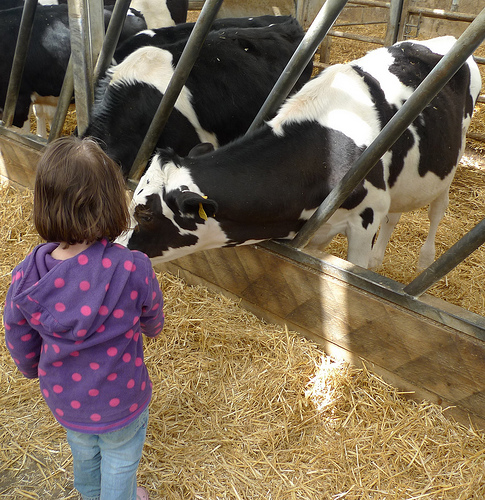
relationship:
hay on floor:
[1, 4, 483, 499] [0, 6, 483, 500]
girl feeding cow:
[2, 132, 169, 500] [104, 26, 483, 315]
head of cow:
[103, 141, 226, 277] [104, 26, 483, 315]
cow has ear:
[104, 26, 483, 315] [172, 185, 219, 223]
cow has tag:
[104, 26, 483, 315] [196, 192, 211, 223]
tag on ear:
[196, 192, 211, 223] [172, 185, 219, 223]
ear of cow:
[172, 185, 219, 223] [104, 26, 483, 315]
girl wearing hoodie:
[2, 132, 169, 500] [2, 237, 165, 434]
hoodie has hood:
[2, 237, 165, 434] [13, 241, 132, 347]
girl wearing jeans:
[2, 132, 169, 500] [61, 406, 151, 500]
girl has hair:
[2, 132, 169, 500] [28, 133, 151, 253]